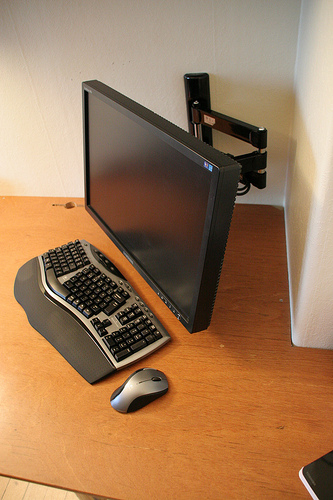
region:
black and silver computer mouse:
[108, 366, 170, 414]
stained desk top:
[0, 194, 332, 499]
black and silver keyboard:
[13, 238, 170, 385]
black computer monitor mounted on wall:
[78, 72, 268, 333]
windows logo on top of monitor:
[202, 160, 214, 171]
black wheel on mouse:
[149, 375, 160, 382]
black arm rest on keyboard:
[13, 255, 114, 383]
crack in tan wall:
[6, 9, 69, 196]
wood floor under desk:
[0, 475, 83, 498]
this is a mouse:
[119, 379, 166, 408]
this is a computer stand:
[185, 80, 268, 142]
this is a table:
[74, 416, 222, 475]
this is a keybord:
[28, 238, 138, 357]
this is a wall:
[296, 37, 324, 303]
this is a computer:
[51, 73, 212, 393]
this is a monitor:
[104, 92, 197, 235]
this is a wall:
[14, 33, 63, 156]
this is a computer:
[286, 458, 332, 493]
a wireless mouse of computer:
[100, 362, 174, 420]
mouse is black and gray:
[107, 364, 173, 417]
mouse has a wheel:
[125, 363, 171, 399]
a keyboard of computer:
[9, 231, 174, 387]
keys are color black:
[8, 235, 175, 392]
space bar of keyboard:
[40, 265, 70, 304]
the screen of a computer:
[68, 72, 241, 343]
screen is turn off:
[58, 70, 250, 349]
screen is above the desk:
[58, 52, 327, 348]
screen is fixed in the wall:
[127, 57, 284, 216]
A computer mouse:
[104, 361, 182, 419]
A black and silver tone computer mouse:
[104, 364, 177, 414]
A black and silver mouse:
[110, 363, 178, 423]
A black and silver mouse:
[106, 363, 180, 420]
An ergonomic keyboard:
[10, 235, 176, 382]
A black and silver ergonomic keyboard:
[16, 233, 173, 386]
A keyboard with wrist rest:
[12, 234, 172, 388]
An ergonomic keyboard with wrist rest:
[12, 235, 170, 385]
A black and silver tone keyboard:
[12, 231, 173, 387]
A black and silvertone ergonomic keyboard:
[12, 235, 173, 387]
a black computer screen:
[70, 78, 243, 331]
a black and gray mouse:
[107, 365, 170, 413]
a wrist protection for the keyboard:
[12, 261, 111, 378]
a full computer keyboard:
[16, 235, 172, 385]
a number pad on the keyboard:
[101, 317, 160, 360]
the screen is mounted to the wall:
[182, 72, 271, 189]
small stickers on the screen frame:
[201, 160, 214, 172]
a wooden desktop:
[0, 196, 331, 496]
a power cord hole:
[62, 200, 76, 208]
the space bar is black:
[44, 266, 69, 298]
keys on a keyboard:
[89, 313, 107, 332]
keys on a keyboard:
[137, 322, 162, 340]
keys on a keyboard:
[119, 299, 142, 318]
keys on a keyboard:
[110, 284, 126, 300]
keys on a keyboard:
[83, 293, 98, 314]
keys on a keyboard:
[93, 268, 109, 287]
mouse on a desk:
[105, 366, 173, 417]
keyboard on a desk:
[3, 236, 131, 384]